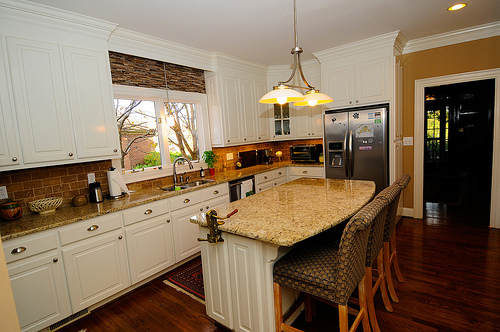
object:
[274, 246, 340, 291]
cushions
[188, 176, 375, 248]
counter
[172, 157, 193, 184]
faucet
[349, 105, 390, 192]
fridge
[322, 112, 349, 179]
freezer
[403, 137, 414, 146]
light switch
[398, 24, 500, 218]
wall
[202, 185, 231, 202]
drawers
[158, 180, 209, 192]
sink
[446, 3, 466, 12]
light fixture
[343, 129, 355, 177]
handles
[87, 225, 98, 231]
handle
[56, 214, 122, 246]
drawer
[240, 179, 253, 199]
towel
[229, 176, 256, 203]
dishwasher handle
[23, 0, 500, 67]
ceiling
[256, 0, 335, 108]
lamp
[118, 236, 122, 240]
knob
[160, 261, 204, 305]
rug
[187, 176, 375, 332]
island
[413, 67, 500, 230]
door frame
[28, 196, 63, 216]
basket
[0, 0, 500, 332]
kitchen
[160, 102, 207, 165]
windows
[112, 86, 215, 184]
frame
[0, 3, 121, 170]
cabinets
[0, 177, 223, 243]
counter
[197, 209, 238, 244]
grip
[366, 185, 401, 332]
chair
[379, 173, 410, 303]
chair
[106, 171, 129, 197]
towels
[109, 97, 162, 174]
window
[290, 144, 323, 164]
oven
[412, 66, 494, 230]
door way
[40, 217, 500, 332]
floor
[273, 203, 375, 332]
bar seat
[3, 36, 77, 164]
door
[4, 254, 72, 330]
door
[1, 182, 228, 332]
cabinet